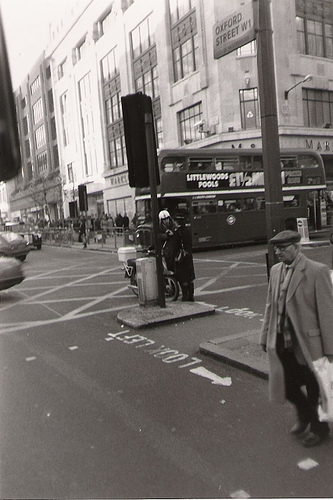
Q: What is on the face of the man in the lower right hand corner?
A: Glasses.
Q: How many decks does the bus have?
A: Two.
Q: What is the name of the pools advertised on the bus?
A: Littlewoods.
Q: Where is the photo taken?
A: Street.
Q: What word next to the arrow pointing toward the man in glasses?
A: Look.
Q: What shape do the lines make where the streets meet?
A: Diamonds.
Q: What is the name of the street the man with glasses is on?
A: Oxford Street W1.